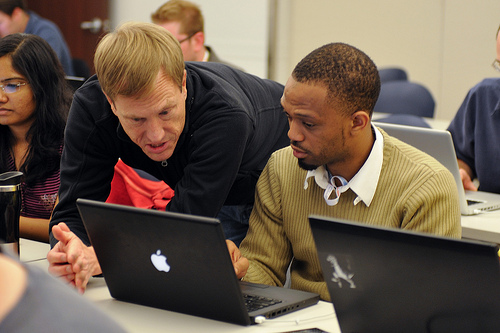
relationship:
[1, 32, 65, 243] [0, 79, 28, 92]
woman wearing glasses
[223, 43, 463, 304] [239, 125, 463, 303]
man wearing a shirt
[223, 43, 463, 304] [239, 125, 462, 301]
man has a sweater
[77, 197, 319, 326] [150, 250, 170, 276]
computer has a logo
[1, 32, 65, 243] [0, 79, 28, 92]
woman has on glasses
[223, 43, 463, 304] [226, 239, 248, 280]
man has hands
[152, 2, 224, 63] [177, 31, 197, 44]
man wearing glasses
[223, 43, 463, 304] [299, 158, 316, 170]
man has a beard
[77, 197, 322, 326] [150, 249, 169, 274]
computer has an icon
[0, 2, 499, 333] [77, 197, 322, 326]
photo of computer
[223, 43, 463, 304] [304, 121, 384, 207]
man has a collar